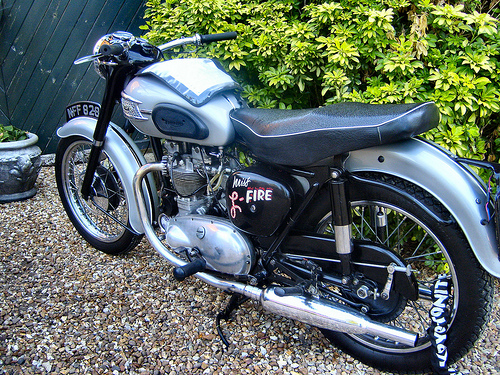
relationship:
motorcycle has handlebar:
[79, 31, 398, 306] [75, 28, 273, 74]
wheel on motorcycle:
[50, 133, 162, 236] [79, 31, 398, 306]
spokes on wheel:
[73, 148, 101, 194] [50, 133, 162, 236]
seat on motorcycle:
[282, 87, 452, 151] [64, 25, 499, 374]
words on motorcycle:
[416, 278, 462, 359] [64, 25, 499, 374]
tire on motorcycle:
[357, 198, 499, 314] [64, 25, 499, 374]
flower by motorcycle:
[0, 105, 33, 172] [64, 25, 499, 374]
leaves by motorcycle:
[241, 21, 331, 84] [64, 25, 499, 374]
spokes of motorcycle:
[73, 148, 101, 194] [64, 25, 499, 374]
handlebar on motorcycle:
[75, 28, 273, 74] [64, 25, 499, 374]